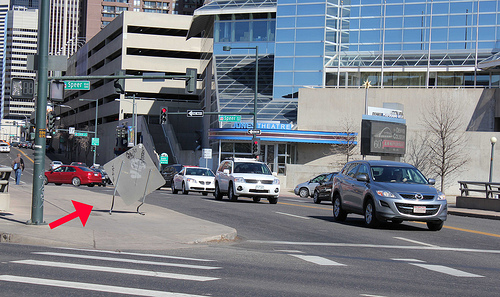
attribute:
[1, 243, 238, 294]
stripes — white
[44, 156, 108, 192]
car — red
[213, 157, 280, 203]
suv — white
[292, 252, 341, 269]
paint — white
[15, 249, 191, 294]
crosswalk — white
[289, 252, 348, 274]
line — white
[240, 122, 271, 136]
sign — blue 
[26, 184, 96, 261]
arrow — red 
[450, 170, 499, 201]
median — metal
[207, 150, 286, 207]
van — white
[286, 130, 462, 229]
car — small, white, compact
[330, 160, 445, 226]
mini van — gray 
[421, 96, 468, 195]
tree — brown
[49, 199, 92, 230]
arrow — red 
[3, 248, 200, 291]
line — white